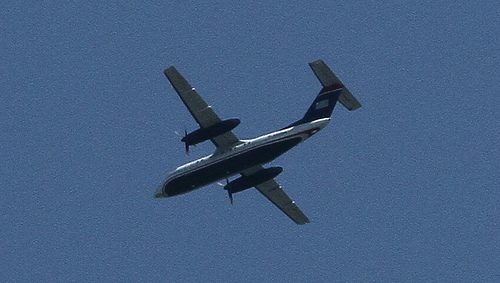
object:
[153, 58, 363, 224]
plane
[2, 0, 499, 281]
blue sky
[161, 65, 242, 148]
left wing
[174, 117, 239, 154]
engine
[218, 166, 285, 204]
engine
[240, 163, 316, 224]
right wing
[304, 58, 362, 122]
verticle stabilizer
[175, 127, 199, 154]
propellor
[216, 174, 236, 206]
propellor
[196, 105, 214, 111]
elevator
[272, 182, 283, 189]
horizonal stabilizer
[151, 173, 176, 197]
nose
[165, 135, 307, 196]
belly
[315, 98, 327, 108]
small white square